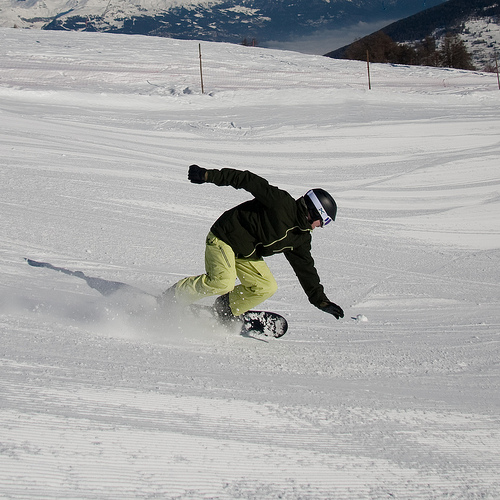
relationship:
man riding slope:
[162, 150, 349, 347] [3, 31, 499, 499]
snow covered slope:
[7, 32, 499, 496] [3, 31, 499, 499]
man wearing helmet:
[162, 150, 349, 347] [303, 187, 340, 228]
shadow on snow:
[33, 256, 149, 307] [7, 32, 499, 496]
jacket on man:
[210, 165, 321, 303] [162, 150, 349, 347]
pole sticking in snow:
[197, 44, 211, 94] [7, 32, 499, 496]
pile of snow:
[156, 84, 203, 99] [7, 32, 499, 496]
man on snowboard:
[162, 150, 349, 347] [142, 299, 286, 349]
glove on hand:
[183, 162, 210, 191] [182, 164, 209, 185]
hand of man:
[182, 164, 209, 185] [162, 150, 349, 347]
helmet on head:
[303, 187, 340, 228] [292, 184, 339, 235]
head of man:
[292, 184, 339, 235] [162, 150, 349, 347]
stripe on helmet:
[313, 191, 328, 212] [303, 187, 340, 228]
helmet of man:
[303, 187, 340, 228] [162, 150, 349, 347]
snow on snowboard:
[7, 32, 499, 496] [142, 299, 286, 349]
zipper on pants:
[216, 245, 236, 268] [161, 235, 285, 327]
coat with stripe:
[210, 165, 321, 303] [243, 230, 290, 259]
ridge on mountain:
[388, 0, 452, 27] [316, 0, 495, 71]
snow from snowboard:
[128, 308, 216, 337] [142, 299, 286, 349]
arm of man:
[281, 248, 343, 320] [162, 150, 349, 347]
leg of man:
[170, 239, 234, 303] [162, 150, 349, 347]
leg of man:
[195, 258, 278, 325] [162, 150, 349, 347]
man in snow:
[162, 150, 349, 347] [7, 32, 499, 496]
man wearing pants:
[162, 150, 349, 347] [161, 235, 285, 327]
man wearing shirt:
[162, 150, 349, 347] [210, 165, 321, 303]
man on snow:
[162, 150, 349, 347] [7, 32, 499, 496]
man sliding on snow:
[162, 150, 349, 347] [7, 32, 499, 496]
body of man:
[199, 178, 305, 293] [162, 150, 349, 347]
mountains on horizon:
[2, 3, 362, 58] [0, 23, 495, 37]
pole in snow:
[197, 44, 211, 94] [7, 32, 499, 496]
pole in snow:
[361, 48, 375, 90] [7, 32, 499, 496]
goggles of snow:
[306, 191, 336, 229] [7, 32, 499, 496]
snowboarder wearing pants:
[162, 150, 349, 347] [161, 235, 285, 327]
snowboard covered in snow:
[142, 299, 286, 349] [7, 32, 499, 496]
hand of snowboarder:
[182, 164, 209, 185] [162, 150, 349, 347]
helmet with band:
[303, 187, 340, 228] [311, 191, 324, 219]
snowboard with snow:
[142, 299, 286, 349] [128, 308, 216, 337]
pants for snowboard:
[161, 235, 285, 327] [142, 299, 286, 349]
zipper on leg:
[216, 245, 236, 268] [170, 239, 234, 303]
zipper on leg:
[216, 245, 236, 268] [195, 258, 278, 325]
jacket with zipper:
[210, 165, 321, 303] [271, 243, 294, 255]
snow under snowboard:
[7, 32, 499, 496] [142, 299, 286, 349]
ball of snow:
[353, 312, 371, 328] [7, 32, 499, 496]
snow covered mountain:
[7, 32, 499, 496] [316, 0, 495, 71]